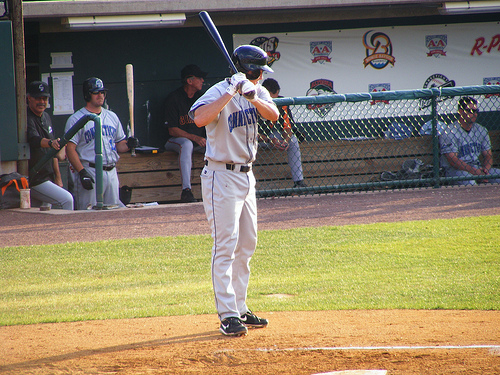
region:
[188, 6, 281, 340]
a baseball player at bat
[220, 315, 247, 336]
a black and white cleated shoe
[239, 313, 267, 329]
a black and white cleated shoe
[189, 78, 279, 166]
a grey and blue baseball jersey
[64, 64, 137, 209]
a baseball player in dugout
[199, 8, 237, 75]
a blue baseball bat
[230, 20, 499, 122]
a white banner advertisement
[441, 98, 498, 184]
a baseball player seated in dugout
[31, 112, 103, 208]
a green handrail in dugout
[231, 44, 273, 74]
a dark blue protective helmet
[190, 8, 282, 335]
man holding a bat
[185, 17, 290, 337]
man wearing a helmet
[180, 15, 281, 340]
man wearing gray shirt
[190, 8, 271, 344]
man wearing gray pants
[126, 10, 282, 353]
man wearing black shoes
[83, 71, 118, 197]
man wearing a helmet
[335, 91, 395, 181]
fence around a field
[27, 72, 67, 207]
man wearing a cap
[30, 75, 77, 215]
man wearing gray pants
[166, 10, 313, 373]
man wearing white gloves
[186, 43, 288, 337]
man standing in the dirt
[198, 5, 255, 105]
black bat held by the batter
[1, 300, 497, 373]
dirt area near the plate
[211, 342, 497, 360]
white line in the dirt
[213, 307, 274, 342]
batter's black nike shoes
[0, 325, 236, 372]
batter's shadow in the dirt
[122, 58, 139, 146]
tan bat in a man's hand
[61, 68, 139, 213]
man in dugout holding a tan bat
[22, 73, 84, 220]
man holding a green rail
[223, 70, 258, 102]
batter's white gloves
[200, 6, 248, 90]
a black bat in a man's hands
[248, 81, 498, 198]
a chain link fence at a dugout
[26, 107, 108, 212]
a green rail at a dugout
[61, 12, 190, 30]
a ceiling light in a dugout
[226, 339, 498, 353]
a white line on a baseball field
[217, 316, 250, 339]
a black and white shoe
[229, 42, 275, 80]
a black helmet on a batter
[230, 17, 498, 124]
a white banner in a dugout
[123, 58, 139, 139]
a wooden bat in a man's hand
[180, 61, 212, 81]
a black cap on a man's head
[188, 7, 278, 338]
a batter stepped out of the batter's box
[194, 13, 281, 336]
hitter toward coach for a sign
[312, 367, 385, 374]
white home plate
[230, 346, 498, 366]
the right handed batter's box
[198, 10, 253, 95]
a baseball bat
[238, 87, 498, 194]
green dugout railing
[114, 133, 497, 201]
long wooden bench in the dugout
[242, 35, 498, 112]
team logos above the bench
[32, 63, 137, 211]
a player and coach by the dugout steps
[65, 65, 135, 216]
player with a bat in his hand in the dugout